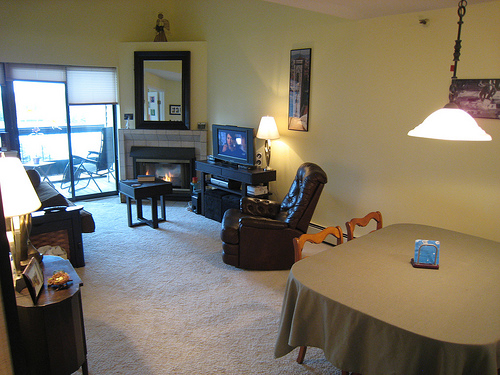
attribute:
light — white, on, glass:
[406, 109, 495, 144]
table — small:
[271, 222, 499, 374]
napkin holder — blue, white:
[409, 238, 441, 271]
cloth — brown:
[272, 222, 499, 372]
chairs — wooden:
[291, 209, 383, 263]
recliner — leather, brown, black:
[218, 162, 327, 275]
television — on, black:
[208, 123, 256, 166]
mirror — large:
[143, 59, 183, 122]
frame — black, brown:
[132, 50, 192, 131]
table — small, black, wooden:
[117, 173, 172, 230]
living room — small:
[1, 0, 353, 373]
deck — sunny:
[24, 160, 121, 201]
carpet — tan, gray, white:
[69, 193, 340, 375]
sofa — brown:
[6, 171, 99, 267]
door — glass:
[3, 65, 120, 205]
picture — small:
[31, 272, 42, 290]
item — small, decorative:
[47, 268, 74, 291]